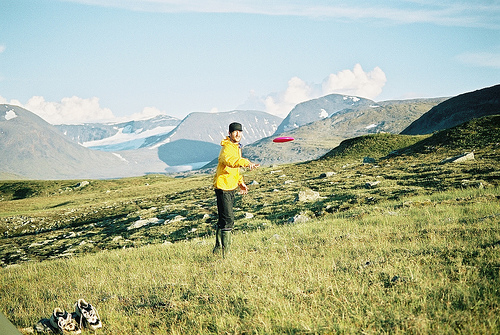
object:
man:
[212, 121, 259, 255]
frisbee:
[271, 136, 295, 142]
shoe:
[75, 298, 100, 329]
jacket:
[214, 138, 249, 191]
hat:
[229, 122, 243, 131]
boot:
[221, 228, 233, 258]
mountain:
[0, 104, 282, 179]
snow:
[4, 108, 19, 120]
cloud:
[0, 94, 123, 128]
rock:
[295, 184, 321, 204]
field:
[0, 116, 499, 333]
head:
[228, 123, 242, 144]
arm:
[217, 149, 248, 167]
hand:
[244, 160, 258, 169]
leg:
[217, 191, 236, 253]